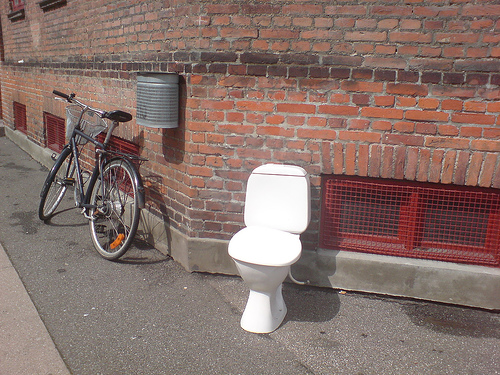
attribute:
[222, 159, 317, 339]
toilet — white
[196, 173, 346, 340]
toilet — down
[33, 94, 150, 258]
shadow — Dark 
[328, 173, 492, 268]
window — rectangular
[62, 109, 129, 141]
basket — Silver 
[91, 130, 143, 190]
panes — red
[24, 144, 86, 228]
wheel — black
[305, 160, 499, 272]
window — red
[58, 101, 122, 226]
bicycle — leaning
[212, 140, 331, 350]
toilet — White 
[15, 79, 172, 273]
bicycle — Black 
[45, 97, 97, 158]
basket — gray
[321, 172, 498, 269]
grates — Red 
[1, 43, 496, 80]
bricks — Dark 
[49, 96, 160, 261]
bicycle — big, black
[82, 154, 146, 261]
back wheel — black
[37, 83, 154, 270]
bicycle — Black 